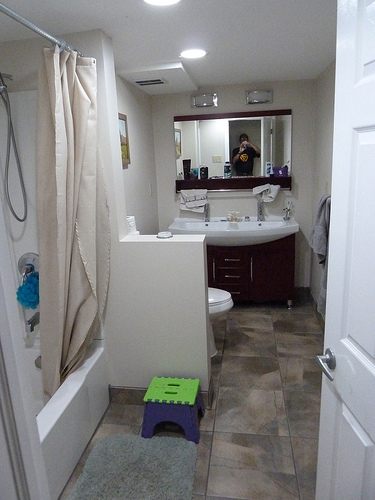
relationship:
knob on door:
[312, 347, 346, 384] [312, 0, 374, 498]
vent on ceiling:
[127, 76, 172, 101] [1, 1, 337, 97]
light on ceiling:
[174, 46, 212, 67] [136, 18, 223, 50]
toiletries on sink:
[212, 209, 233, 221] [166, 211, 300, 244]